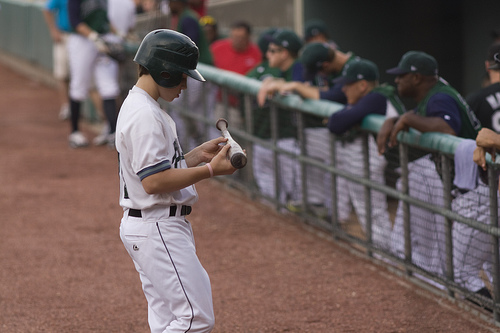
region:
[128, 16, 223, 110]
the helmet is green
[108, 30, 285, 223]
boy holding a bat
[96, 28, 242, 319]
this i a baseball player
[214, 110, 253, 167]
this is a bat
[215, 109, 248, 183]
the bat i wooden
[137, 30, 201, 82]
he is wearing helmet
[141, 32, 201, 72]
the helmet is green in color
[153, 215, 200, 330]
the trousers is white in color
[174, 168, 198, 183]
this is the hand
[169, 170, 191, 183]
the hand is white in color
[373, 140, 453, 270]
this is a fence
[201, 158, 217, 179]
this is a wrist band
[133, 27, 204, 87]
The helmet is green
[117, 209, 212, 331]
The pants are white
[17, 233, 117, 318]
Dirt on the ground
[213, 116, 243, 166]
A base ball bat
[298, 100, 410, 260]
A green metal fence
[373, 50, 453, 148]
The man is black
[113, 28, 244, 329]
Kid holding a bat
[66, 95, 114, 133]
The socks are black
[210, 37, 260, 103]
The shirt is red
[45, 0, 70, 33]
The shirt is blue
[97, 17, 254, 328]
a boy holding a baseball bat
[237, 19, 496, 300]
men leaning over the barrier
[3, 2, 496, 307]
the barrier is metal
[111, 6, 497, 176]
the barrier top is green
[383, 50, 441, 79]
the man is wearing a green baseball cap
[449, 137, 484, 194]
a cloth on the barrier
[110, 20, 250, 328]
the boy is looking at a baseball bat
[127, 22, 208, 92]
he is wearing a helmet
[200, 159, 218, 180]
he has a pink bracelet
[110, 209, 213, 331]
he is wearing white pants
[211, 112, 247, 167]
wooden baseball bat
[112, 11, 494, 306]
teammates watch the game from the dugout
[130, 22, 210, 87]
dark blue protective batting helmet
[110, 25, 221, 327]
baseball player in a white uniform with dark blue batting helmet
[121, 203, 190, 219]
baseball uniform belt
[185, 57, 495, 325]
protective railing and fencing in front of the dugout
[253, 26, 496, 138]
teammates hang their arms over the railing as they watch the action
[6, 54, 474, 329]
red dirt on the baseball field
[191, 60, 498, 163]
green padded railing protecting players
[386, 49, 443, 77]
soft dark blue baseball cap